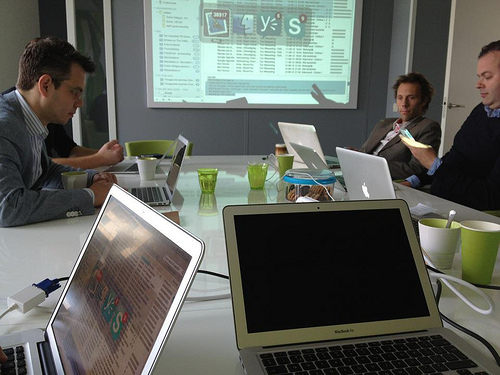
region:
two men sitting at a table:
[354, 40, 499, 213]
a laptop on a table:
[221, 198, 496, 374]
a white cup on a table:
[136, 155, 158, 178]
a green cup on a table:
[459, 215, 499, 283]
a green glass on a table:
[196, 165, 217, 194]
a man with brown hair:
[18, 35, 93, 129]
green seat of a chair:
[126, 138, 191, 159]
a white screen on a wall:
[141, 0, 362, 109]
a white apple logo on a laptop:
[361, 180, 371, 199]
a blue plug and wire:
[34, 267, 226, 311]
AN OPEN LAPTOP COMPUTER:
[218, 197, 494, 371]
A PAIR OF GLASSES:
[56, 76, 91, 100]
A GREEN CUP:
[457, 218, 498, 290]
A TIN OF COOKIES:
[278, 165, 338, 203]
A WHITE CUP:
[135, 148, 160, 183]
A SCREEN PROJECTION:
[141, 1, 368, 113]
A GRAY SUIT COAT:
[2, 86, 99, 230]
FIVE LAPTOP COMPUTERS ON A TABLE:
[1, 117, 497, 372]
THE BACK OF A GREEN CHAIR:
[123, 137, 193, 161]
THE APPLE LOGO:
[359, 178, 373, 200]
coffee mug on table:
[134, 155, 157, 179]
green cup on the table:
[200, 165, 217, 185]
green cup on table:
[248, 163, 263, 187]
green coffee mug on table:
[273, 153, 298, 168]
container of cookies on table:
[285, 165, 337, 197]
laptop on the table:
[116, 136, 198, 206]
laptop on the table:
[268, 114, 335, 158]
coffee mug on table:
[421, 212, 450, 266]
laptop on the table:
[211, 200, 481, 374]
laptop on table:
[3, 186, 203, 373]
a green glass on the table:
[196, 165, 218, 191]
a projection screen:
[146, 2, 358, 107]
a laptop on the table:
[221, 198, 498, 374]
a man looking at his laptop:
[2, 35, 192, 220]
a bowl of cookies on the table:
[284, 168, 334, 200]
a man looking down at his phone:
[398, 40, 499, 211]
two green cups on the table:
[418, 210, 497, 289]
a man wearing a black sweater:
[438, 39, 496, 202]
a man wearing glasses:
[2, 38, 104, 220]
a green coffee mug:
[270, 153, 295, 178]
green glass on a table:
[193, 163, 220, 198]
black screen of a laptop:
[246, 212, 387, 313]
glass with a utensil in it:
[421, 211, 461, 273]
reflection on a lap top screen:
[92, 228, 156, 324]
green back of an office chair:
[121, 131, 186, 174]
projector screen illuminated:
[176, 13, 326, 93]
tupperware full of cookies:
[281, 165, 336, 205]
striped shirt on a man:
[24, 111, 51, 161]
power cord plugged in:
[9, 258, 60, 321]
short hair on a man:
[17, 48, 82, 93]